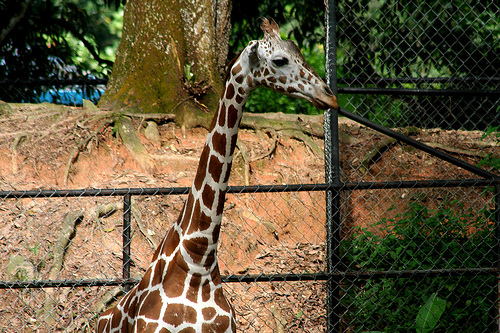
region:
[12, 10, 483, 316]
giraffe by fencing and hill of dirt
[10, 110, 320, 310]
tree roots spreading in reddish soil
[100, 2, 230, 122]
base of tree trunk covered in white spots and moss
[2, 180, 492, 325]
wires over metal poles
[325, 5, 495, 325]
slanted bar over higher fencing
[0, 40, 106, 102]
bright blue car in back of leaves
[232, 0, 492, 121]
trees and plants behind giraffe head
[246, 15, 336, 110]
narrow and pointy head of giraffe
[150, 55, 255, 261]
narrow neck widening at base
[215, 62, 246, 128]
brown squares around middle shape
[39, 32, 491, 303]
a giraffe in a fenced in area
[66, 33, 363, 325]
a giraffe standing behind a fence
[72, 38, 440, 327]
a giraffe standing in a field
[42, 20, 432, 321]
a giraffe with a long neck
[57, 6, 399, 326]
a long neck giraffe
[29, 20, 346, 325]
a long neck giraffe fenced in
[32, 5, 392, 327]
a giraffe with a long neck fenced in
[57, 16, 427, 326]
a tall giraffe behind a fence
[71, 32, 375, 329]
a long neck giraffe behind a fence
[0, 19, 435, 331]
a giraffe with a long neck behind the fence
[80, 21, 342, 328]
A giraffe appeared to need a company.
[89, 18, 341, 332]
A giraffe standing alone.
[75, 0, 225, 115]
A big tree trunk behind a giraffe.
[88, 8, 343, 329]
White and brown giraffe.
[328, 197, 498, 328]
Green bushes near the fence.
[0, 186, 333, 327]
Short mental fence.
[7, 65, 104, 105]
A hidden swimming pool.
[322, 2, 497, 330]
Tall fences protecting the plants from the giraffe.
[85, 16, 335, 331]
A giraffe sitting on the ground.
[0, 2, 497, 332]
A wealthy person's backyard.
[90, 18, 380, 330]
a giraffe in a zoo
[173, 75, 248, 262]
the neck of a giraffe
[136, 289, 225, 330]
the spots of a giraffe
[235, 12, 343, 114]
the head of a giraffe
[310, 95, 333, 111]
the mouth of a giraffe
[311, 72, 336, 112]
the nose of a giraffe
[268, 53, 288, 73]
the eye of a giraffe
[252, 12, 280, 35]
the horns of a giraffe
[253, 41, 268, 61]
the ear of a giraffe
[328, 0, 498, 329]
a chain link fence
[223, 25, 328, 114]
head of the giraffe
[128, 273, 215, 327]
brown spots on the giraffe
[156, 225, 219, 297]
white lines on the giraffe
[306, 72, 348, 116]
nose of the giraffe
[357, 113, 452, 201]
fence behind the giraffe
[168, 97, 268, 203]
neck of the giraffe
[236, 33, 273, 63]
ear of the giraffe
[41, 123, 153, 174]
dirt behind the giraffe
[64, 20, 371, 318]
one giraffe in the photo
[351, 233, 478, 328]
leaves behind the fence